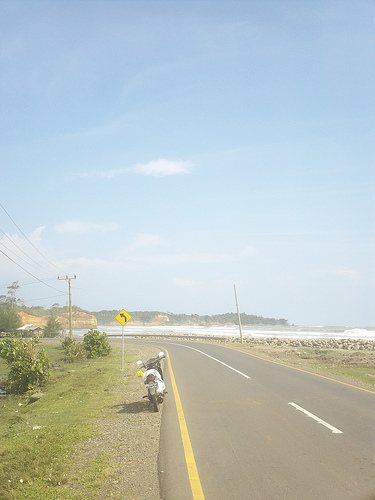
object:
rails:
[93, 332, 225, 344]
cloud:
[109, 148, 196, 196]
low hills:
[1, 301, 295, 334]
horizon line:
[1, 292, 373, 319]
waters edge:
[62, 323, 373, 343]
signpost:
[115, 309, 132, 370]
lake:
[54, 306, 373, 358]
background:
[1, 19, 373, 350]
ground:
[281, 118, 299, 138]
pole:
[121, 326, 124, 370]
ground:
[48, 333, 153, 498]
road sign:
[115, 308, 131, 326]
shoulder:
[231, 342, 369, 389]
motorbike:
[136, 351, 168, 412]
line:
[287, 401, 343, 434]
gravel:
[77, 354, 163, 478]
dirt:
[102, 479, 161, 496]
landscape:
[0, 308, 374, 498]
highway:
[0, 336, 373, 498]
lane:
[103, 328, 374, 500]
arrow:
[119, 312, 127, 322]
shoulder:
[66, 336, 166, 497]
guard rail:
[102, 334, 230, 347]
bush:
[80, 328, 109, 357]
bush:
[0, 334, 49, 397]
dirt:
[113, 401, 142, 456]